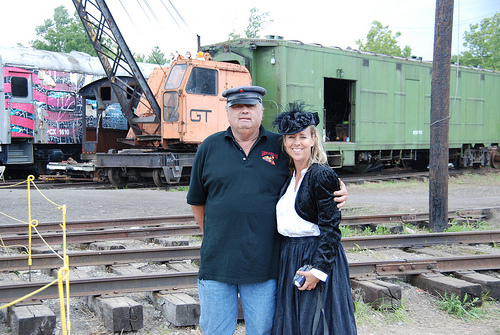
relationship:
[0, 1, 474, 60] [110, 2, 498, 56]
clouds in sky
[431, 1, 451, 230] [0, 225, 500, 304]
pole in middle of track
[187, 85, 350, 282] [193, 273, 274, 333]
man wearing jeans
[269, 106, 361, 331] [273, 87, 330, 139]
woman wearing hat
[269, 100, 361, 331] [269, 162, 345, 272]
woman wearing jacket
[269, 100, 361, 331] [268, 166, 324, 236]
woman wearing shirt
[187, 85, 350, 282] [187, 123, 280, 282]
man wearing black shirt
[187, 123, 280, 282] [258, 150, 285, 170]
black shirt with logo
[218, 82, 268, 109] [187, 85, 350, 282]
black hat worn by man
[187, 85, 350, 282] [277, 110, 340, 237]
man has arm around lady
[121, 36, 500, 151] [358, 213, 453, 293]
train on track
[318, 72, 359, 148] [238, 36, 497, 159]
open door on train car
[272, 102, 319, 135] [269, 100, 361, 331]
hat worn by woman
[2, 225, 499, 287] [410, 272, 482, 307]
track on block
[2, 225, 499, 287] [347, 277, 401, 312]
track on block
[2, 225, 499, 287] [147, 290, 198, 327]
track on block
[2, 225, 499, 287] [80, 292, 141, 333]
track on block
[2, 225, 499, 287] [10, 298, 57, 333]
track on block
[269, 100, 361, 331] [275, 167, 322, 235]
woman wearing a blouse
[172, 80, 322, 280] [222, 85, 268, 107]
man wearing a black hat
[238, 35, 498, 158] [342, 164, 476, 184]
train on train track